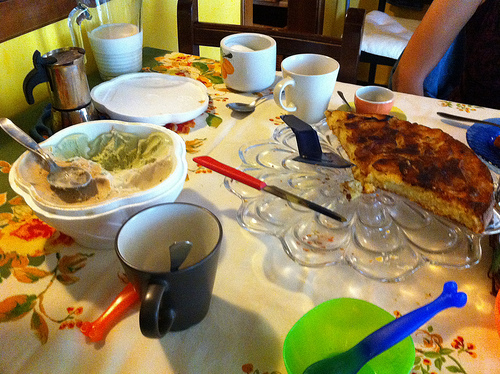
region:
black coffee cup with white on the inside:
[92, 191, 232, 341]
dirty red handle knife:
[180, 141, 367, 258]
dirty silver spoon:
[0, 103, 138, 215]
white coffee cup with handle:
[260, 52, 365, 139]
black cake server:
[245, 110, 370, 189]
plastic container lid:
[85, 56, 209, 158]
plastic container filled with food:
[0, 104, 207, 256]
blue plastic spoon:
[283, 267, 476, 372]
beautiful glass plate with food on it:
[216, 107, 497, 290]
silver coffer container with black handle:
[20, 34, 92, 151]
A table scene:
[7, 5, 494, 369]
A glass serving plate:
[236, 131, 478, 280]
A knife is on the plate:
[194, 140, 359, 239]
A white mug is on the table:
[274, 40, 343, 120]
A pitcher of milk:
[71, 0, 158, 79]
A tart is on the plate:
[319, 98, 492, 245]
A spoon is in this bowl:
[0, 105, 114, 231]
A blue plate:
[466, 108, 498, 162]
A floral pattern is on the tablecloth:
[0, 215, 88, 343]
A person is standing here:
[395, 0, 498, 109]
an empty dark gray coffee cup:
[115, 201, 222, 338]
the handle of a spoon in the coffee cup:
[169, 240, 193, 268]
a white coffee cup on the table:
[272, 52, 340, 122]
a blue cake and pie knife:
[279, 112, 354, 169]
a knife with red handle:
[192, 153, 346, 223]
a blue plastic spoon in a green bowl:
[299, 280, 467, 372]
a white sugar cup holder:
[221, 31, 276, 89]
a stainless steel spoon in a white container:
[0, 117, 90, 187]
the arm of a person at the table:
[387, 2, 498, 89]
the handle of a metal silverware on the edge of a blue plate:
[435, 110, 498, 167]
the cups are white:
[209, 24, 349, 132]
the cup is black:
[93, 189, 257, 342]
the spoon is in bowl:
[0, 104, 213, 234]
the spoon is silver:
[1, 109, 106, 213]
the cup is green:
[273, 276, 400, 373]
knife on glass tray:
[203, 125, 358, 235]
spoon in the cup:
[156, 221, 196, 273]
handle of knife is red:
[198, 147, 270, 199]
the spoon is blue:
[299, 270, 496, 368]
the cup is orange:
[348, 79, 403, 141]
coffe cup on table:
[110, 198, 225, 343]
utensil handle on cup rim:
[162, 231, 199, 273]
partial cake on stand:
[246, 111, 487, 270]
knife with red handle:
[192, 153, 345, 221]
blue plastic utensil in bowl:
[332, 278, 471, 371]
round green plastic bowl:
[285, 286, 414, 372]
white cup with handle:
[269, 46, 344, 123]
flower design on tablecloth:
[7, 226, 79, 335]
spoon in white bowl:
[6, 119, 137, 201]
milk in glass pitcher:
[71, 6, 148, 77]